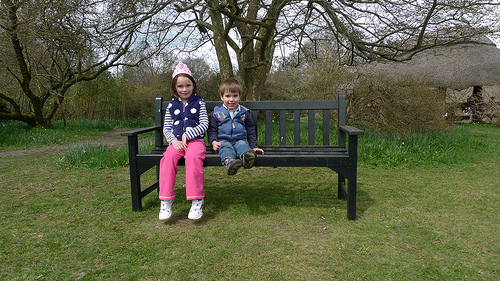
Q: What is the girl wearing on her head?
A: Crown.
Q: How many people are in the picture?
A: Two.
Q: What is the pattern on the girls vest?
A: Polka dots.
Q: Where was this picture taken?
A: Park.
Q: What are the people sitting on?
A: Bench.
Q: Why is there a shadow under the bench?
A: It's sunny.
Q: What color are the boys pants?
A: Blue.